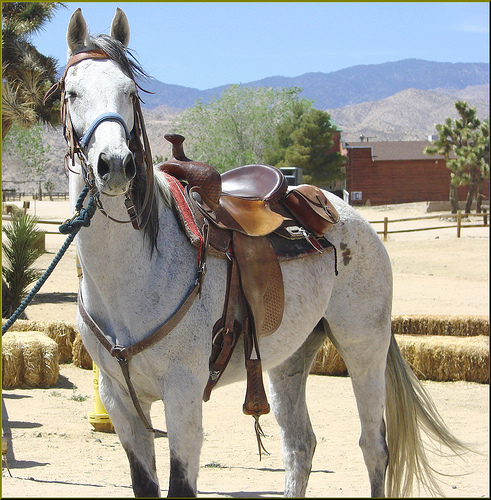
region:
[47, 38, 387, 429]
one horse is seen.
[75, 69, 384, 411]
Horse is white color.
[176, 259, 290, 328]
Straps are brown color.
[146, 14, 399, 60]
Sky is blue color.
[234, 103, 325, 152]
leaves are green color.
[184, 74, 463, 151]
Mountains are behind the horse.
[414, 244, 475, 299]
Ground is brown color.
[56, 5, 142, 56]
Two pointed ears for horse.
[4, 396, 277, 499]
Shadow falls on ground.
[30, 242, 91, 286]
Rope is blue color.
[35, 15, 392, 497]
this is a horse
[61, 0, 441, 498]
the horse is big in size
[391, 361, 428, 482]
the tail is wavy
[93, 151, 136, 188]
the nose are wide open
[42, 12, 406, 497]
the horse is white in color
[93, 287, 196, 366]
a belt is tied on the horse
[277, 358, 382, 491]
the horse has strong legs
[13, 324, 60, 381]
these are hays for the horse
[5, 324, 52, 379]
the hays are well arranged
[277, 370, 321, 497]
the leg is in front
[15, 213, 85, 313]
this is a rope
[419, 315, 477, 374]
this is a hey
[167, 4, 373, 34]
this is the sky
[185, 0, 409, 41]
the sky is blue in color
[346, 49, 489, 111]
these are mountains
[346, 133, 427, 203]
this is a building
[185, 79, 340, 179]
this is a tree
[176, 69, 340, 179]
the tree is green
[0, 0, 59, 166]
this is a palm tree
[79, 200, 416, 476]
this is a horse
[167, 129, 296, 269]
Brown saddle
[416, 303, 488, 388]
Bails of hay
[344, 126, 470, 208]
Red building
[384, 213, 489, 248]
Wooden fence in front of red building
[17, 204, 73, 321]
Blue rope tied to white horse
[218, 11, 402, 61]
Clear blue sky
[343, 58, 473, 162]
Mountains behind red building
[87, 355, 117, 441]
Yellow barrel behind white horse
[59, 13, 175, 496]
White horse standing on sandy ground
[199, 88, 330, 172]
Row of trees in front of mountains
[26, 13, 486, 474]
A picture of a horse.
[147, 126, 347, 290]
There is a saddle on the horse.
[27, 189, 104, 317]
The rope is blue.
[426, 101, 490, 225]
The tree is green.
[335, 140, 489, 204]
A building in the background.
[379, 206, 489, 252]
A fence in the background.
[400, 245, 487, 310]
The ground is dirt covered.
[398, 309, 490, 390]
The horse is surrounded by straw.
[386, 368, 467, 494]
The horse has a blonde tail.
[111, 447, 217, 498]
The horse has black on the front legs.